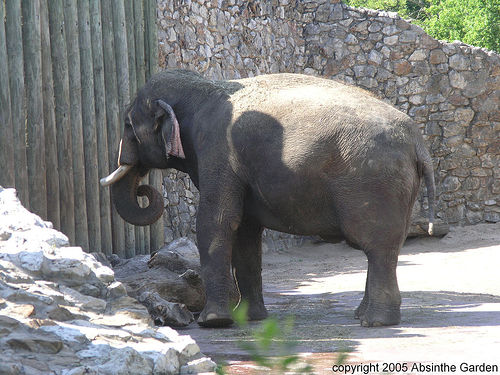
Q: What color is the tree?
A: Green.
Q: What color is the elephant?
A: Grey.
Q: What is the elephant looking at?
A: The gate.